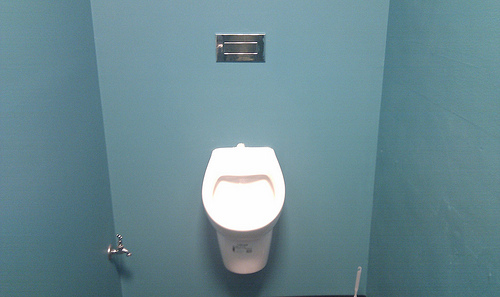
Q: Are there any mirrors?
A: No, there are no mirrors.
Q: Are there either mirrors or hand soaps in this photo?
A: No, there are no mirrors or hand soaps.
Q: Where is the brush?
A: The brush is on the floor.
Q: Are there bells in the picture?
A: No, there are no bells.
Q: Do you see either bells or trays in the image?
A: No, there are no bells or trays.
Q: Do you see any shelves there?
A: No, there are no shelves.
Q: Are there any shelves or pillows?
A: No, there are no shelves or pillows.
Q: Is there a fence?
A: No, there are no fences.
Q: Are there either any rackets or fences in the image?
A: No, there are no fences or rackets.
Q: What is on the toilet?
A: The logo is on the toilet.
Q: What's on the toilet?
A: The logo is on the toilet.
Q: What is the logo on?
A: The logo is on the toilet.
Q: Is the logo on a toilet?
A: Yes, the logo is on a toilet.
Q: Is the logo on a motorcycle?
A: No, the logo is on a toilet.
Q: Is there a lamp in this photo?
A: No, there are no lamps.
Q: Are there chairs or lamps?
A: No, there are no lamps or chairs.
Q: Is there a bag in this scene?
A: No, there are no bags.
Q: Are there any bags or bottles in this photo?
A: No, there are no bags or bottles.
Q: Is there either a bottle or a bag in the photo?
A: No, there are no bags or bottles.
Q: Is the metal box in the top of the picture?
A: Yes, the box is in the top of the image.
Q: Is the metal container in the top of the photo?
A: Yes, the box is in the top of the image.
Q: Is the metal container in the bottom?
A: No, the box is in the top of the image.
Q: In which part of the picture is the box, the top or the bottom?
A: The box is in the top of the image.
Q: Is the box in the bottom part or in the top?
A: The box is in the top of the image.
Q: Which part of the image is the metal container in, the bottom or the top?
A: The box is in the top of the image.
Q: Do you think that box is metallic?
A: Yes, the box is metallic.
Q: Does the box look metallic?
A: Yes, the box is metallic.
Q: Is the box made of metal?
A: Yes, the box is made of metal.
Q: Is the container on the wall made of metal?
A: Yes, the box is made of metal.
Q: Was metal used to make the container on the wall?
A: Yes, the box is made of metal.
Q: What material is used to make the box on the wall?
A: The box is made of metal.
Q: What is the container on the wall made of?
A: The box is made of metal.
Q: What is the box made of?
A: The box is made of metal.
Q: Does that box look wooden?
A: No, the box is metallic.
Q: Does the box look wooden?
A: No, the box is metallic.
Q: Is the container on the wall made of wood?
A: No, the box is made of metal.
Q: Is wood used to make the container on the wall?
A: No, the box is made of metal.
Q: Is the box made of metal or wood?
A: The box is made of metal.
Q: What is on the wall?
A: The box is on the wall.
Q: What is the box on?
A: The box is on the wall.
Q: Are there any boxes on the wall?
A: Yes, there is a box on the wall.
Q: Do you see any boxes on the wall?
A: Yes, there is a box on the wall.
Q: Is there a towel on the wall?
A: No, there is a box on the wall.